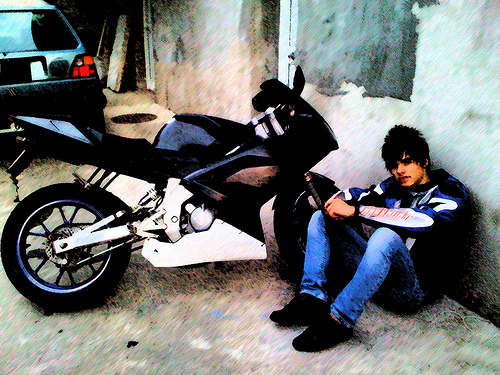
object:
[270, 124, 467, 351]
boy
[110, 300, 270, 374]
ground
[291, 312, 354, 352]
shoes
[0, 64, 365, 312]
motorcycle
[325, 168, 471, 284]
jacket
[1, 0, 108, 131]
car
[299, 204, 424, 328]
jeans